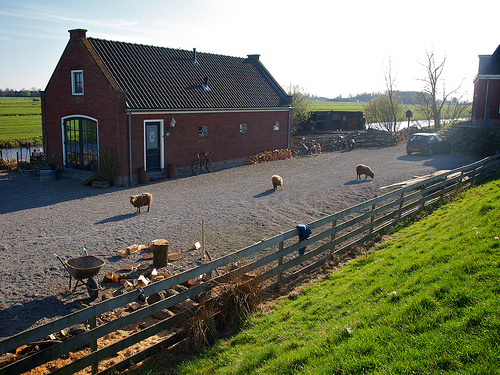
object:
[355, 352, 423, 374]
grass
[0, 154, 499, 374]
fence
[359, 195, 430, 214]
wood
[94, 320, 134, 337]
wood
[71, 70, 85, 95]
window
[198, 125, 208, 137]
window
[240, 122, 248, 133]
window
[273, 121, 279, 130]
window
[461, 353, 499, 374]
grass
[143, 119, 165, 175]
door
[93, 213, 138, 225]
shadow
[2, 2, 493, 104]
sky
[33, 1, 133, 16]
blue sky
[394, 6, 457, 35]
white cloud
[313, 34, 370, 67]
white cloud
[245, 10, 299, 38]
white cloud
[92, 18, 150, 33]
white cloud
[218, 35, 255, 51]
white cloud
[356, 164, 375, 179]
animal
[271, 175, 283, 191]
animal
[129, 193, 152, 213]
animal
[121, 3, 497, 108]
cloud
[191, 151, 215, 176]
bicycle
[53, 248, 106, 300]
wheelbarrow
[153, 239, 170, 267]
logs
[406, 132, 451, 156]
car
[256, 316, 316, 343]
green grass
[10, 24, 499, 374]
farm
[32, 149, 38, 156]
man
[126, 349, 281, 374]
grass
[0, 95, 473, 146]
grass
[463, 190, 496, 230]
grass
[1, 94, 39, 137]
grass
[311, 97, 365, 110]
grass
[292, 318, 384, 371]
part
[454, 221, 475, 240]
part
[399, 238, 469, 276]
part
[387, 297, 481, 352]
part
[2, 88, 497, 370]
country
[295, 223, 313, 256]
jacket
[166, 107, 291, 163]
wall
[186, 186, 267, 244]
gravel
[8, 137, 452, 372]
road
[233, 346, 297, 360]
part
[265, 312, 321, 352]
part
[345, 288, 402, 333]
part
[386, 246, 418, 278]
part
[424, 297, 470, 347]
part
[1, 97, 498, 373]
ground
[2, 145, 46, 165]
creek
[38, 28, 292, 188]
house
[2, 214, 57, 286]
gravel